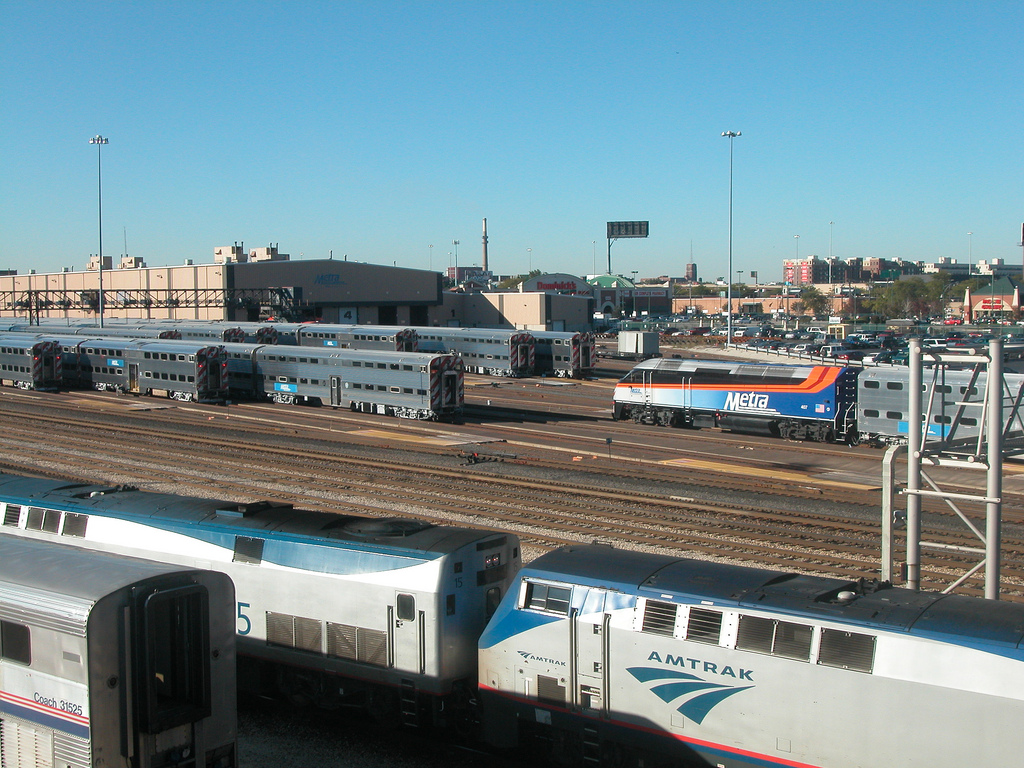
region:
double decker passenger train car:
[250, 341, 467, 424]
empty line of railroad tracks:
[2, 394, 1021, 559]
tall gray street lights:
[718, 126, 744, 360]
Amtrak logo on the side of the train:
[625, 650, 762, 728]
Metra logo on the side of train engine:
[721, 388, 782, 420]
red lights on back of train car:
[29, 351, 62, 364]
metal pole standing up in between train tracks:
[875, 337, 1016, 601]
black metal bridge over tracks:
[0, 285, 302, 321]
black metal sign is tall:
[604, 217, 653, 297]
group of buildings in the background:
[777, 253, 1022, 288]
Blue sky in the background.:
[98, 37, 1022, 502]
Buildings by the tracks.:
[119, 188, 894, 648]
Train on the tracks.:
[363, 446, 627, 713]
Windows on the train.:
[508, 533, 872, 711]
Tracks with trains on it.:
[215, 280, 589, 767]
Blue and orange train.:
[556, 264, 869, 455]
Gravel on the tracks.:
[337, 302, 638, 577]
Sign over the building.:
[577, 182, 717, 318]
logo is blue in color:
[615, 637, 770, 730]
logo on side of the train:
[623, 638, 760, 756]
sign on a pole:
[580, 204, 676, 256]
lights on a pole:
[56, 116, 143, 161]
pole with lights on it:
[82, 156, 120, 318]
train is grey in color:
[208, 331, 499, 414]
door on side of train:
[305, 362, 357, 420]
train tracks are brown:
[8, 368, 874, 555]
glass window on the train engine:
[813, 627, 872, 669]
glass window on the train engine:
[770, 615, 810, 655]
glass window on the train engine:
[729, 615, 769, 648]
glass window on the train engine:
[232, 536, 256, 562]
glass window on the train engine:
[61, 504, 80, 528]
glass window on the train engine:
[36, 504, 57, 528]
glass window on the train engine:
[20, 501, 40, 522]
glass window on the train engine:
[0, 615, 29, 669]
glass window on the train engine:
[393, 595, 414, 616]